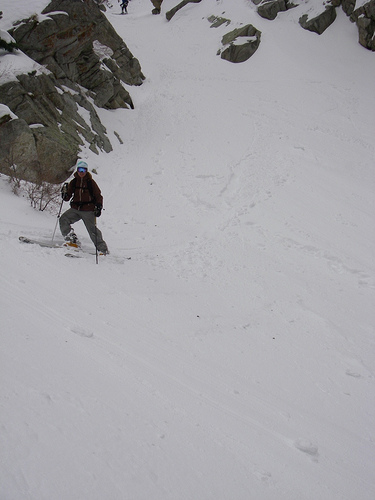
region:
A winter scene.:
[3, 1, 372, 477]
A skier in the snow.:
[15, 153, 115, 266]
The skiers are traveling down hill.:
[0, 0, 373, 265]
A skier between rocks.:
[65, 1, 253, 115]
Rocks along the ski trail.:
[3, 2, 374, 215]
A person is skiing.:
[16, 156, 126, 272]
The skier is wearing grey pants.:
[20, 153, 130, 273]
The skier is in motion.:
[13, 156, 131, 277]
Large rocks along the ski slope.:
[2, 2, 152, 201]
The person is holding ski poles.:
[14, 156, 125, 269]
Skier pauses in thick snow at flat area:
[36, 159, 107, 259]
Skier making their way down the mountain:
[112, 0, 140, 16]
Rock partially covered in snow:
[205, 11, 270, 71]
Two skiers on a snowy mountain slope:
[22, 0, 280, 260]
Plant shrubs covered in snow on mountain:
[5, 147, 57, 217]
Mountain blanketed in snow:
[187, 64, 320, 216]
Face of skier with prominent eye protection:
[73, 163, 95, 179]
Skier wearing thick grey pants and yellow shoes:
[54, 207, 119, 260]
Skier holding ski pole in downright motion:
[53, 178, 69, 242]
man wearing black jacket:
[55, 174, 106, 216]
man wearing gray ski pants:
[58, 206, 105, 247]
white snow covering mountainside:
[7, 4, 359, 489]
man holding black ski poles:
[47, 191, 105, 267]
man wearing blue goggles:
[77, 166, 86, 172]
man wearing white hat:
[76, 157, 88, 168]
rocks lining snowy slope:
[78, 159, 85, 164]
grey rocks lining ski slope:
[0, 0, 371, 183]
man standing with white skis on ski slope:
[17, 160, 117, 272]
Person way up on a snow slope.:
[120, 0, 130, 12]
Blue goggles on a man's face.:
[75, 166, 87, 175]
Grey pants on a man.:
[56, 207, 108, 253]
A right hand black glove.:
[61, 181, 68, 197]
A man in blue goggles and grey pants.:
[58, 161, 108, 255]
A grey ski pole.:
[50, 185, 67, 246]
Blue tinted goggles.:
[76, 166, 87, 173]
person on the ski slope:
[58, 160, 110, 255]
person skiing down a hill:
[118, 0, 128, 13]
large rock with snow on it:
[298, 3, 337, 34]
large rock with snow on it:
[254, 0, 297, 19]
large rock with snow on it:
[2, 31, 120, 182]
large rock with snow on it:
[9, 1, 145, 109]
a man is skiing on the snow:
[21, 120, 199, 342]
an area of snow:
[113, 314, 312, 479]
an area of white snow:
[72, 287, 298, 454]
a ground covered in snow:
[69, 301, 323, 498]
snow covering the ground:
[115, 357, 291, 492]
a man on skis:
[24, 147, 116, 267]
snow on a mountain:
[210, 10, 299, 106]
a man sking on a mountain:
[13, 128, 245, 266]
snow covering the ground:
[147, 111, 293, 254]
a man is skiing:
[39, 160, 150, 306]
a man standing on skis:
[47, 138, 179, 282]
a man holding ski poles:
[60, 160, 93, 230]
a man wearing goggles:
[38, 146, 120, 247]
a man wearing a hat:
[73, 157, 94, 207]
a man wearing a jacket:
[54, 160, 97, 225]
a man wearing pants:
[68, 165, 127, 278]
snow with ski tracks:
[37, 72, 257, 225]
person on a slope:
[57, 155, 115, 258]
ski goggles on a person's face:
[75, 162, 88, 174]